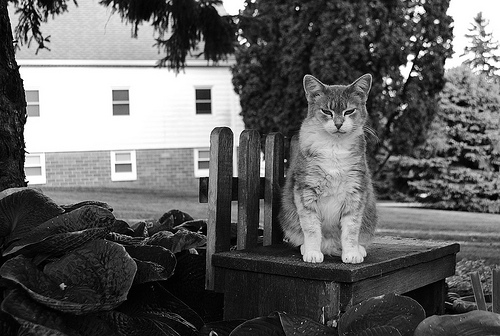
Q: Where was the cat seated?
A: On table.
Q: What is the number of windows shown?
A: 6.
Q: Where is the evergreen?
A: Right.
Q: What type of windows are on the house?
A: Double hung.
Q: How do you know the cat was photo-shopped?
A: White outline.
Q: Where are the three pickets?
A: Left of cat.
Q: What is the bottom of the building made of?
A: Brick.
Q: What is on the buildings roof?
A: Shingles.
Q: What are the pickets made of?
A: Wood.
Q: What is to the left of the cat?
A: Fence posts.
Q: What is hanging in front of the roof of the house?
A: Tree limbs.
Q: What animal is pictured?
A: Cat.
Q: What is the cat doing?
A: Sitting.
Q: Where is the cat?
A: On the bench.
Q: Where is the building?
A: Behind the cat.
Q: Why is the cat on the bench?
A: To rest.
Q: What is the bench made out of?
A: Wood.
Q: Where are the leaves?
A: On the tree.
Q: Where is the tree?
A: Behind the cat.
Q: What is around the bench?
A: Cabbage.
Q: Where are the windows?
A: On the building.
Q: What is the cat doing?
A: Looking at camera.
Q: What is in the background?
A: A house.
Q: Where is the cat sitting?
A: A chair.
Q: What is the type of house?
A: Multi storied.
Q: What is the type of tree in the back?
A: Tall and thick.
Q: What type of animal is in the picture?
A: A cat.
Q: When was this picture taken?
A: During the day.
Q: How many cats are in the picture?
A: One.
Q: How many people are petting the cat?
A: Zero.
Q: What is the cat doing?
A: Sitting.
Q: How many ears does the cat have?
A: Two.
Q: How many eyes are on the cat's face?
A: Two.